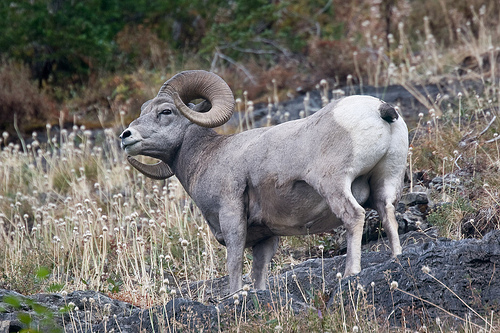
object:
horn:
[162, 75, 243, 123]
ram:
[122, 68, 431, 305]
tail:
[379, 101, 403, 128]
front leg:
[223, 239, 249, 296]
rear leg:
[328, 202, 369, 276]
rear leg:
[375, 195, 405, 276]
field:
[19, 138, 499, 294]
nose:
[114, 127, 139, 141]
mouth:
[111, 138, 151, 152]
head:
[117, 94, 221, 164]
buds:
[42, 199, 146, 225]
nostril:
[126, 132, 130, 137]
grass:
[32, 35, 499, 102]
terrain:
[241, 67, 499, 144]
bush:
[20, 11, 147, 89]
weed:
[55, 238, 480, 332]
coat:
[222, 147, 322, 188]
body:
[249, 139, 341, 217]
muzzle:
[118, 139, 153, 156]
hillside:
[29, 34, 499, 206]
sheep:
[125, 59, 434, 247]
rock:
[444, 56, 489, 92]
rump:
[344, 102, 415, 180]